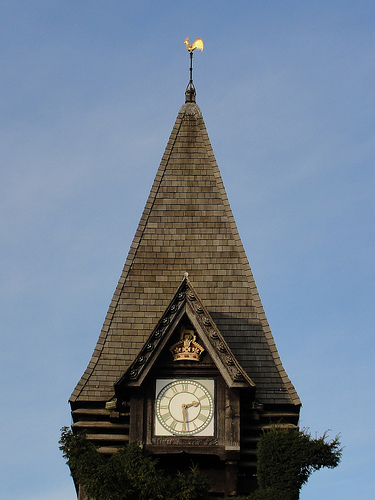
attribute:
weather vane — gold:
[183, 33, 206, 68]